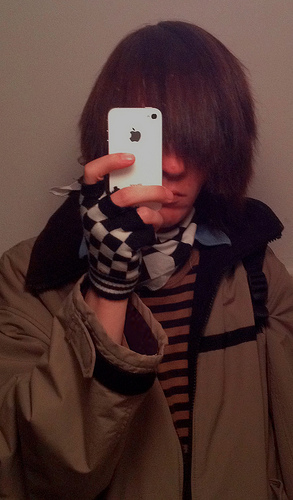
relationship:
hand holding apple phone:
[73, 155, 178, 239] [103, 104, 162, 199]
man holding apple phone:
[0, 20, 293, 500] [103, 104, 162, 199]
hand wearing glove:
[78, 152, 173, 285] [79, 189, 154, 303]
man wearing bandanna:
[0, 20, 293, 500] [79, 208, 197, 293]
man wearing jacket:
[0, 20, 293, 500] [12, 275, 287, 489]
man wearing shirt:
[0, 20, 293, 500] [133, 245, 208, 433]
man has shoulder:
[10, 16, 289, 498] [176, 191, 288, 333]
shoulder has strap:
[176, 191, 288, 333] [236, 238, 274, 330]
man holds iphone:
[10, 16, 289, 498] [103, 102, 174, 197]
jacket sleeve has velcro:
[3, 271, 168, 499] [93, 343, 156, 399]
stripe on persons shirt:
[135, 249, 199, 453] [36, 119, 284, 414]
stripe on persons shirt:
[145, 293, 191, 328] [110, 250, 202, 443]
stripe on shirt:
[135, 249, 199, 453] [131, 246, 206, 483]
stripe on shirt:
[135, 249, 199, 453] [150, 260, 201, 449]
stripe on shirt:
[135, 249, 199, 453] [131, 245, 197, 462]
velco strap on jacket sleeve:
[72, 342, 134, 395] [0, 272, 168, 498]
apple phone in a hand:
[106, 107, 163, 213] [71, 165, 180, 332]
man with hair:
[0, 20, 293, 500] [77, 28, 264, 217]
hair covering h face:
[77, 28, 264, 217] [135, 110, 202, 253]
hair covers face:
[77, 20, 262, 209] [140, 139, 212, 228]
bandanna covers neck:
[49, 173, 196, 290] [156, 224, 201, 243]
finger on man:
[78, 146, 134, 188] [10, 16, 289, 498]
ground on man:
[232, 95, 253, 120] [10, 16, 289, 498]